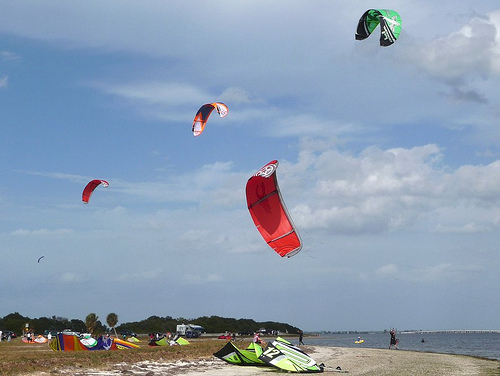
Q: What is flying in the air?
A: Parasails.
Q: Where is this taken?
A: Beach.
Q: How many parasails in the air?
A: Five.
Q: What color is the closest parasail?
A: Red.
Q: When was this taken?
A: Daytime.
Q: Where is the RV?
A: Bottom center.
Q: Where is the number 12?
A: On center grounded parasail.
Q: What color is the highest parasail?
A: Blue and green.